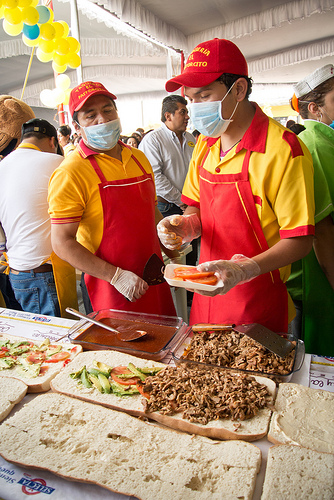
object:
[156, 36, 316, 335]
man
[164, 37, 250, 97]
hat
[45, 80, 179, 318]
man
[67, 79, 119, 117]
hat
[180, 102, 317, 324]
shirt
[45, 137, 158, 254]
shirt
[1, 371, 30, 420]
bread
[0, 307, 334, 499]
table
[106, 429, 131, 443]
guacamole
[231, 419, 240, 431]
meat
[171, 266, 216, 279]
tomatoes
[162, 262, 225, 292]
tray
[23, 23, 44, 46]
balloons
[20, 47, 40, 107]
stick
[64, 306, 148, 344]
spoon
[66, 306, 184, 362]
baking dish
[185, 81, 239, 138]
mask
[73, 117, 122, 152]
mask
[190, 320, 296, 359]
spatula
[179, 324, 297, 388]
meat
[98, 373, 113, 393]
food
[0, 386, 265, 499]
slice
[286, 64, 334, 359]
woman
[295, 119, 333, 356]
shirt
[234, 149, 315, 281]
arm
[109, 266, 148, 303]
glove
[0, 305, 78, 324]
edge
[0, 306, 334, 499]
cloth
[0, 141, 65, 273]
back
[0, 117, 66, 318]
person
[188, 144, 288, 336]
apron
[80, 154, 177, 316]
apron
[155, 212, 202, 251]
gloves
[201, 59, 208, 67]
lettering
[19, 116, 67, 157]
hat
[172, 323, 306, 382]
dishes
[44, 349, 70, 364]
vegetables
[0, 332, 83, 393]
slices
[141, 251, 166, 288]
spatula